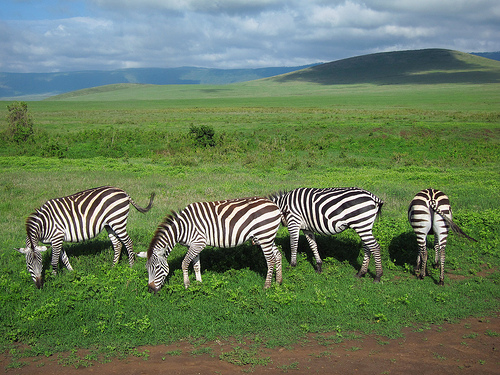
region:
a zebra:
[0, 174, 150, 332]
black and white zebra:
[11, 176, 149, 270]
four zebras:
[20, 165, 498, 282]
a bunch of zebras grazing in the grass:
[22, 166, 497, 311]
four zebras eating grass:
[18, 140, 495, 310]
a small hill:
[258, 10, 469, 85]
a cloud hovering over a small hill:
[255, 0, 495, 105]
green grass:
[65, 88, 422, 186]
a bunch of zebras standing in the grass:
[17, 103, 488, 334]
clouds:
[28, 7, 415, 64]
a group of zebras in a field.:
[12, 170, 469, 312]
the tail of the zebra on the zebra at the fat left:
[124, 190, 166, 220]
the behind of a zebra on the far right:
[411, 186, 461, 241]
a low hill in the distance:
[296, 42, 486, 117]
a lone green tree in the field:
[179, 116, 226, 156]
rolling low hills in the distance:
[9, 67, 274, 106]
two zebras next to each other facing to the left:
[143, 200, 399, 287]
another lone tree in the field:
[9, 101, 39, 153]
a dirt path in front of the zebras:
[132, 330, 328, 372]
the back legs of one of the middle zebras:
[254, 235, 288, 295]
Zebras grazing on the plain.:
[15, 178, 482, 300]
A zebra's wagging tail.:
[130, 190, 160, 215]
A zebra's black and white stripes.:
[310, 190, 365, 225]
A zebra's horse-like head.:
[135, 250, 170, 290]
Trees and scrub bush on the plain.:
[0, 95, 485, 170]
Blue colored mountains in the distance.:
[5, 55, 285, 95]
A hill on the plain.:
[271, 41, 492, 81]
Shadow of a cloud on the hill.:
[281, 43, 493, 97]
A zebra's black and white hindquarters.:
[408, 183, 463, 255]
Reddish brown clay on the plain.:
[7, 338, 495, 370]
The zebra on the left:
[14, 177, 139, 292]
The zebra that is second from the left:
[144, 188, 286, 298]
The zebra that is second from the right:
[279, 187, 395, 284]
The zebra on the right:
[404, 179, 481, 290]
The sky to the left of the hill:
[1, 0, 302, 90]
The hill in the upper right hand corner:
[273, 29, 499, 93]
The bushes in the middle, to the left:
[3, 93, 241, 170]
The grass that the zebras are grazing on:
[2, 255, 499, 367]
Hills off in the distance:
[3, 47, 283, 98]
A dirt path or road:
[5, 322, 497, 373]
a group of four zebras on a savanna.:
[16, 178, 486, 305]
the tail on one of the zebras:
[136, 194, 166, 219]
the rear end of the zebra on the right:
[414, 194, 452, 239]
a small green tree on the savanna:
[181, 118, 228, 159]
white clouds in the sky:
[39, 12, 218, 62]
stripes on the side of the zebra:
[211, 208, 268, 238]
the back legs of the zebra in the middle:
[349, 234, 395, 285]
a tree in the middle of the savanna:
[7, 98, 44, 164]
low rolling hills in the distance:
[4, 55, 294, 126]